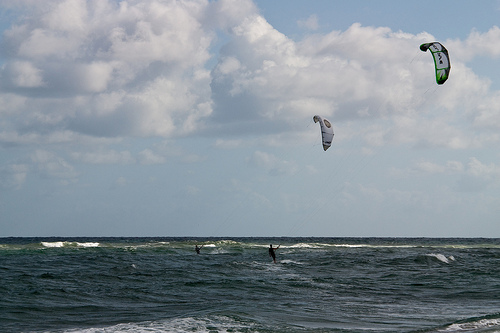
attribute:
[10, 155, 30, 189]
cloud — puffy 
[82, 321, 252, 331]
foam — white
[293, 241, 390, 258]
ocean wave — pictured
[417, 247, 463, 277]
froth — white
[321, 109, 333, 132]
circle — red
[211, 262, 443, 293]
wave — white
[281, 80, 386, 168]
kite — white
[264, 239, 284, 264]
person — surfing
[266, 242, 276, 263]
person — silhouette of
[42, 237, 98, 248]
caps — white